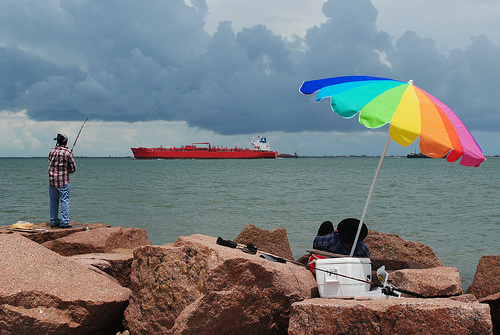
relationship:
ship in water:
[128, 136, 280, 164] [0, 158, 498, 258]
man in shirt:
[44, 130, 83, 240] [45, 147, 79, 189]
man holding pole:
[44, 130, 83, 240] [68, 119, 88, 157]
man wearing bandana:
[44, 130, 83, 240] [58, 133, 68, 144]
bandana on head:
[58, 133, 68, 144] [53, 132, 70, 146]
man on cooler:
[312, 217, 372, 253] [313, 255, 374, 302]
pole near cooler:
[68, 119, 88, 157] [313, 255, 374, 302]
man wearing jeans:
[44, 130, 83, 240] [46, 184, 72, 227]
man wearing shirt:
[44, 130, 83, 240] [45, 147, 79, 189]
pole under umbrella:
[329, 137, 398, 255] [289, 70, 497, 261]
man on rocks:
[44, 130, 83, 240] [8, 223, 497, 334]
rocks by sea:
[8, 223, 497, 334] [0, 158, 498, 258]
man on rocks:
[312, 217, 372, 253] [8, 223, 497, 334]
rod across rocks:
[260, 252, 430, 299] [8, 223, 497, 334]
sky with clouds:
[1, 1, 497, 160] [8, 10, 285, 134]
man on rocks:
[47, 133, 78, 230] [8, 223, 497, 334]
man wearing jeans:
[47, 133, 78, 230] [46, 184, 72, 227]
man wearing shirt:
[47, 133, 78, 230] [45, 147, 79, 189]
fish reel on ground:
[260, 252, 430, 299] [8, 223, 497, 334]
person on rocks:
[312, 217, 372, 253] [8, 223, 497, 334]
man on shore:
[44, 130, 83, 240] [8, 223, 497, 334]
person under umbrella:
[312, 217, 372, 253] [289, 70, 497, 261]